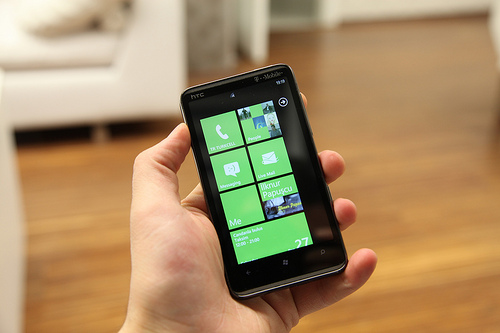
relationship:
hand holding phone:
[117, 91, 379, 332] [180, 63, 348, 300]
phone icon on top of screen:
[215, 124, 231, 140] [188, 76, 338, 265]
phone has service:
[180, 63, 348, 300] [227, 90, 237, 100]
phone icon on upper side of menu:
[215, 124, 231, 140] [198, 102, 314, 265]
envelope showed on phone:
[261, 152, 279, 164] [180, 63, 348, 300]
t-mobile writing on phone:
[253, 71, 285, 83] [180, 63, 348, 300]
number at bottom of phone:
[293, 235, 310, 249] [180, 63, 348, 300]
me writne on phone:
[228, 218, 243, 228] [180, 63, 348, 300]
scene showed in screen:
[262, 192, 302, 220] [188, 76, 338, 265]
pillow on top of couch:
[0, 31, 115, 67] [6, 0, 188, 141]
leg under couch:
[91, 125, 112, 142] [6, 0, 188, 141]